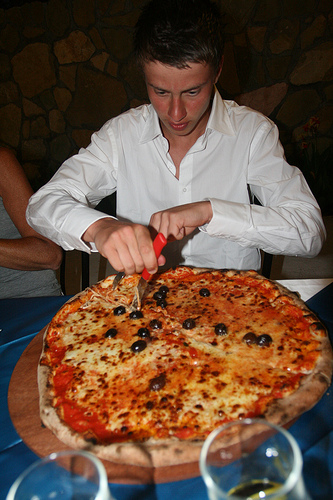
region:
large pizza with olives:
[5, 261, 331, 493]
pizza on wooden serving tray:
[5, 263, 331, 484]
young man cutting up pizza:
[23, 34, 331, 313]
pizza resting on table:
[4, 264, 331, 498]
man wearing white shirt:
[25, 37, 327, 272]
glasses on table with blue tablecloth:
[0, 415, 330, 498]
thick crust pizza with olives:
[35, 264, 331, 473]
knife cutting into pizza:
[111, 219, 185, 326]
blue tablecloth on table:
[1, 292, 332, 497]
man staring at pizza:
[24, 49, 332, 311]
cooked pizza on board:
[46, 274, 318, 456]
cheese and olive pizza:
[51, 268, 317, 460]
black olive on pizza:
[131, 341, 146, 352]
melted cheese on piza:
[181, 376, 255, 423]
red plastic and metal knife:
[131, 235, 167, 315]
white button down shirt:
[49, 104, 313, 272]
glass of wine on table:
[200, 419, 302, 499]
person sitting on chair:
[0, 142, 65, 300]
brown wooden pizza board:
[10, 313, 291, 481]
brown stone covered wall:
[2, 3, 331, 173]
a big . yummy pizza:
[28, 256, 329, 475]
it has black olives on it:
[85, 284, 283, 404]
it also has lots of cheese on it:
[76, 334, 133, 395]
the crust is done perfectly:
[37, 291, 85, 466]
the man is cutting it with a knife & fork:
[78, 211, 234, 333]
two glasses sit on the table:
[0, 415, 309, 498]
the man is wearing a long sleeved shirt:
[22, 72, 331, 297]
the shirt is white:
[23, 91, 331, 306]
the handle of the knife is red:
[133, 216, 173, 319]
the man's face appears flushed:
[138, 16, 236, 146]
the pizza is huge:
[36, 260, 315, 460]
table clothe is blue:
[7, 307, 26, 355]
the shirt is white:
[83, 183, 305, 263]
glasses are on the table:
[3, 441, 300, 499]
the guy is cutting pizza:
[57, 104, 314, 316]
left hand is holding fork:
[155, 209, 230, 235]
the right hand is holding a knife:
[94, 209, 149, 263]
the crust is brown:
[34, 385, 62, 433]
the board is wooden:
[16, 394, 59, 451]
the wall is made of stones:
[31, 47, 109, 125]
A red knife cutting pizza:
[124, 228, 166, 309]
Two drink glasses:
[14, 412, 322, 499]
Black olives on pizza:
[239, 317, 290, 355]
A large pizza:
[31, 264, 332, 467]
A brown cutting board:
[6, 323, 45, 450]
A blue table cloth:
[304, 401, 331, 489]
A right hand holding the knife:
[80, 207, 162, 279]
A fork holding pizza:
[106, 269, 132, 292]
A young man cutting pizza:
[24, 11, 323, 315]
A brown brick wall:
[246, 13, 327, 109]